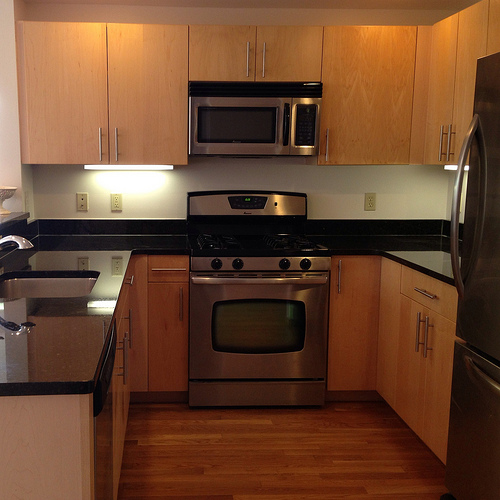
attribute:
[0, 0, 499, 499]
kitchen — modern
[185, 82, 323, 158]
microwave — stainless, off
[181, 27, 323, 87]
cabinets — wood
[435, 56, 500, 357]
refrigerator — stainless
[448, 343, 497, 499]
freezer — stainless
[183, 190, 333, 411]
oven — stainless, silver, black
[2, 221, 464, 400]
counter top — black, granite, wood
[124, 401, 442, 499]
floors — hardwood, wooden, wood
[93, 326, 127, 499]
dishwasher — stainless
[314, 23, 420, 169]
cabinet — wood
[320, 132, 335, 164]
handles — metal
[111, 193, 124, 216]
outlet — electrical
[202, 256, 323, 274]
knobs — black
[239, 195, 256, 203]
writing — green